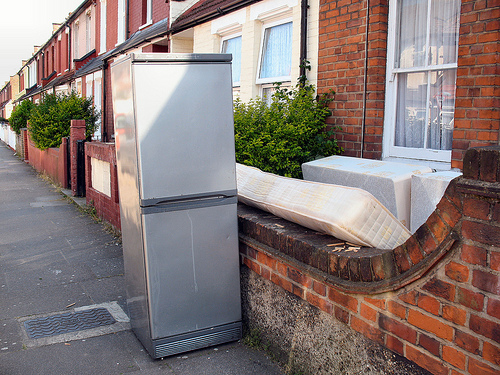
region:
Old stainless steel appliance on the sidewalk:
[104, 49, 249, 364]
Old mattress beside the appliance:
[232, 161, 418, 253]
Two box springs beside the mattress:
[297, 149, 465, 236]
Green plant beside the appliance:
[230, 56, 350, 178]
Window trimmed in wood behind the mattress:
[382, 0, 464, 164]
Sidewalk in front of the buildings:
[1, 137, 296, 374]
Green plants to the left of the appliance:
[1, 83, 105, 156]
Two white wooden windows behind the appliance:
[204, 1, 307, 126]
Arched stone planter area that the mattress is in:
[232, 147, 497, 299]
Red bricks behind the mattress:
[314, 1, 497, 174]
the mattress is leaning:
[307, 179, 368, 267]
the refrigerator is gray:
[153, 108, 195, 153]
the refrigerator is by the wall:
[223, 202, 260, 275]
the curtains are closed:
[401, 82, 424, 126]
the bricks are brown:
[418, 297, 472, 334]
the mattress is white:
[293, 182, 326, 212]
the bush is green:
[251, 114, 281, 145]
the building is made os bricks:
[330, 61, 352, 110]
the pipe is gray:
[354, 36, 374, 71]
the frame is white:
[382, 24, 401, 64]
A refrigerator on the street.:
[107, 31, 246, 363]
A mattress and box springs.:
[241, 98, 461, 295]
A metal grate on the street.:
[14, 291, 124, 358]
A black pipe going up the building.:
[296, 11, 323, 139]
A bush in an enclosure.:
[14, 87, 98, 189]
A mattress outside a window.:
[239, 107, 462, 368]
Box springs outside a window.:
[298, 96, 470, 210]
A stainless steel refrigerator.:
[102, 40, 252, 364]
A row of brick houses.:
[13, 27, 113, 197]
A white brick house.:
[180, 5, 320, 151]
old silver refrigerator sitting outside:
[108, 50, 248, 360]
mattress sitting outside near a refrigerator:
[239, 175, 407, 262]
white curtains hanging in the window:
[388, 0, 455, 154]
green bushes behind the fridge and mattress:
[226, 83, 331, 178]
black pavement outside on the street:
[5, 185, 55, 295]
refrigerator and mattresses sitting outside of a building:
[112, 53, 406, 355]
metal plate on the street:
[22, 305, 115, 341]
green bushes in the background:
[0, 98, 97, 143]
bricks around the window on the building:
[461, 5, 493, 144]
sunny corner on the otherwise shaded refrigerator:
[135, 64, 192, 144]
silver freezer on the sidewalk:
[111, 53, 243, 361]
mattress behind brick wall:
[234, 163, 408, 248]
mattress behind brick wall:
[302, 153, 430, 222]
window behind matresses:
[385, 0, 451, 161]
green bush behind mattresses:
[234, 91, 338, 178]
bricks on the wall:
[237, 185, 498, 373]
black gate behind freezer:
[74, 134, 92, 196]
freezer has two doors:
[133, 61, 243, 328]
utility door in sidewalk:
[20, 305, 115, 335]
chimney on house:
[50, 21, 60, 29]